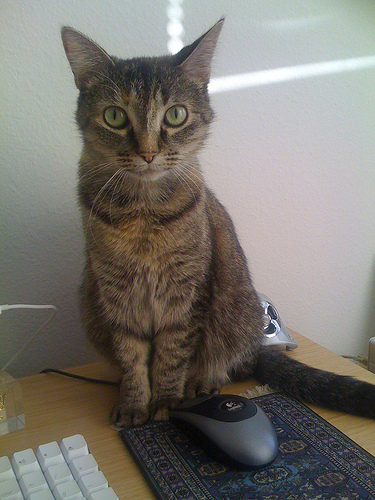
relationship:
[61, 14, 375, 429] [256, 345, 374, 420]
cat has tail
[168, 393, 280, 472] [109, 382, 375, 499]
mouse on top of mousepad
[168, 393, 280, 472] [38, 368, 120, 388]
mouse has cord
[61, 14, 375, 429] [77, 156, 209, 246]
cat has whiskers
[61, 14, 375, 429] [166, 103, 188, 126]
cat has eye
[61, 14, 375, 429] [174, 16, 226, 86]
cat has ear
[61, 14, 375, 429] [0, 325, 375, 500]
cat on top of desk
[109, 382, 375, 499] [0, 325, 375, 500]
mousepad on top of desk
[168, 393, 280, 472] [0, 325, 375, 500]
mouse on top of desk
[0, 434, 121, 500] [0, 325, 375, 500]
keyboard on top of desk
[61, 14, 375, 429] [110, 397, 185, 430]
cat has paws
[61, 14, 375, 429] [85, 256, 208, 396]
cat has legs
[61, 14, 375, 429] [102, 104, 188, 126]
cat has eyes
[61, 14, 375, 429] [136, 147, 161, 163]
cat has nose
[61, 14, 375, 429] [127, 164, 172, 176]
cat has mouth